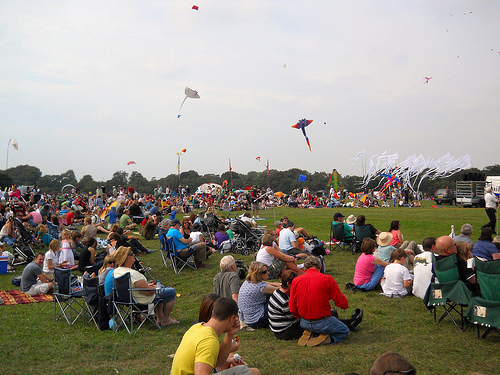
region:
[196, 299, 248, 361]
THIS IS A PERSON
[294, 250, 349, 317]
THIS IS A PERSON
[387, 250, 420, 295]
THIS IS A PERSON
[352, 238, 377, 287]
THIS IS A PERSON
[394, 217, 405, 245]
THIS IS A PERSON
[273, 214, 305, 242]
THIS IS A PERSON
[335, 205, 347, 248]
THIS IS A PERSON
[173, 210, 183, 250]
THIS IS A PERSON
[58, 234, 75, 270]
THIS IS A PERSON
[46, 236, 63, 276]
THIS IS A PERSON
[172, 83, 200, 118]
kite in the sky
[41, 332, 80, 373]
green grass on the groun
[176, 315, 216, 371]
the man's yellow shirt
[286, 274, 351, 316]
the man's red shirt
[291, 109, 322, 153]
purple kite in the sky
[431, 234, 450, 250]
the man's bald head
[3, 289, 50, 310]
blanket on the ground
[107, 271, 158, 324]
folding chair on the ground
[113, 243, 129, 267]
hat on the person's head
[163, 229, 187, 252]
the man's blue shirt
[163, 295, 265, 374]
man in yellow shirt sitting in grassy field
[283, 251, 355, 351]
man in red shirt and blue jeans sitting in grassy field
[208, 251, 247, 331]
man in gray shirt sitting in grassy field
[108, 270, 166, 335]
black chair with gray metal frame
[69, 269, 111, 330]
black chair with gray metal frame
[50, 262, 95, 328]
black chair with gray metal frame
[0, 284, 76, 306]
red yellow and orange rectangular blanket on grassy field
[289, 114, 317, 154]
blue and orange kite flying in the air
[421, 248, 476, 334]
green folding lawn chair in grassy field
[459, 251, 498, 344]
green folding lawn chair in grassy field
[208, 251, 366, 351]
a group of four people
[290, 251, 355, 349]
man kneeling on the grass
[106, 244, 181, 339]
woman sitting in a folding chair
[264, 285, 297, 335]
black and white stripes on the shirt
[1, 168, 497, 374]
a crowd of people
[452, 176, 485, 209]
truck parked on the grass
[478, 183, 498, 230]
man walking on the grass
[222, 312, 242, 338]
hand lifted to the face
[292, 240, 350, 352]
man wearing red shirt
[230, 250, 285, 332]
woman wearing patterned blue shirt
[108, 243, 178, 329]
woman sitting in black chair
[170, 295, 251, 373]
man wearing yellow shirt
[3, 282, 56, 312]
orange and red patterned blanked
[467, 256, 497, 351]
green fabric chair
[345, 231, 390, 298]
woman wearing pink shirt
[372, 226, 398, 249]
tan round hat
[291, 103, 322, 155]
colorful flying kite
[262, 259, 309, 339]
woman wearing black striped shirt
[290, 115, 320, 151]
a large blue and red kite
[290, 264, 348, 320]
a person in a long sleeved red shirt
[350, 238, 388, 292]
a woman in a bright pink shirt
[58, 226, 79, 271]
a little girl in a white dress standing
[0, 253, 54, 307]
a man sitting on a striped blanket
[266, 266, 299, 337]
a woman in a striped shirt beside a person in a red shirt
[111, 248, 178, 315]
a woman in a brown hat and a white shirt sitting in a chair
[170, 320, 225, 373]
a yellow t-shirt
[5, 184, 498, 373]
a crowd of people